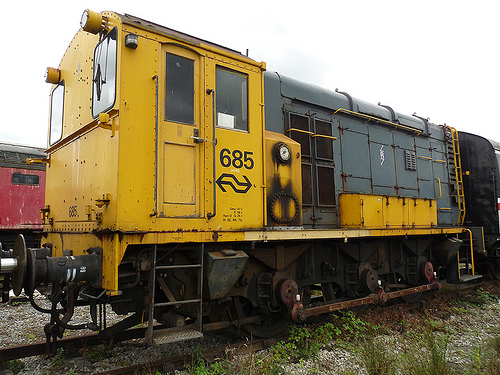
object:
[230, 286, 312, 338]
wheels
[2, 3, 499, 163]
sky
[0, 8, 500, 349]
train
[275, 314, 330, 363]
weed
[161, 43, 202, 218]
door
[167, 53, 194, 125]
window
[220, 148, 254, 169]
numbers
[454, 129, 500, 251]
engine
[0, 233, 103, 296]
plugs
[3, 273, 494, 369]
track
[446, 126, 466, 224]
ladder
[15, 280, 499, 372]
ground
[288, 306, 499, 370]
gravel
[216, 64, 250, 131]
window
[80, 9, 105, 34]
light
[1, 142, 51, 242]
train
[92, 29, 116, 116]
window